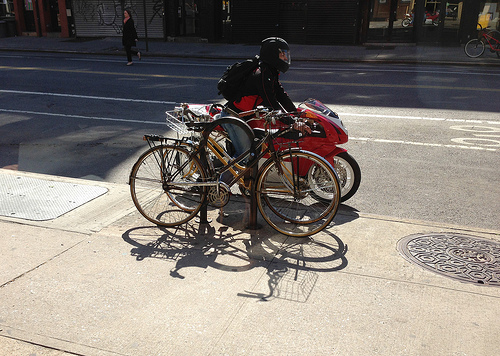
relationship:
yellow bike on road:
[157, 110, 341, 225] [37, 64, 447, 213]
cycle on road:
[128, 106, 365, 200] [12, 52, 139, 171]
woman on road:
[112, 7, 149, 67] [37, 107, 109, 182]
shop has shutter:
[69, 0, 498, 46] [72, 0, 169, 48]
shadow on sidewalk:
[125, 225, 332, 313] [0, 164, 498, 354]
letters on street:
[438, 115, 497, 158] [1, 46, 498, 233]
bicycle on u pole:
[129, 117, 341, 237] [197, 117, 259, 232]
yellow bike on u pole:
[126, 110, 343, 246] [197, 115, 260, 232]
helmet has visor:
[246, 26, 300, 76] [275, 44, 293, 67]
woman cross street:
[121, 7, 143, 67] [4, 39, 193, 193]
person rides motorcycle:
[208, 26, 300, 122] [152, 90, 366, 210]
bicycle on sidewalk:
[129, 117, 341, 237] [0, 164, 498, 354]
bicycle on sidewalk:
[130, 114, 335, 225] [0, 164, 498, 354]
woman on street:
[121, 7, 143, 67] [1, 49, 204, 174]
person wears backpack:
[208, 36, 306, 202] [214, 54, 264, 102]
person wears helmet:
[208, 25, 306, 230] [259, 37, 291, 74]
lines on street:
[1, 88, 498, 125] [1, 46, 498, 233]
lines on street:
[1, 84, 498, 156] [1, 46, 498, 233]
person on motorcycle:
[217, 32, 307, 133] [192, 95, 369, 211]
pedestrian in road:
[116, 8, 146, 72] [9, 42, 490, 354]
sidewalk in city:
[0, 164, 498, 354] [1, 0, 498, 355]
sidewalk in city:
[1, 27, 498, 64] [1, 0, 498, 355]